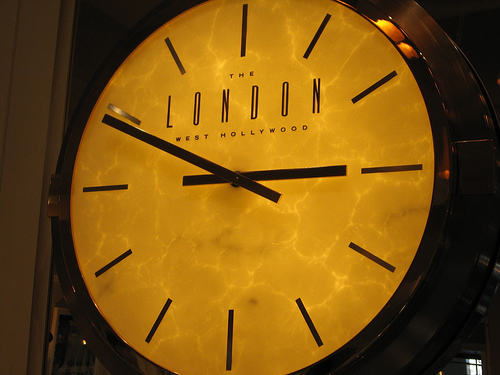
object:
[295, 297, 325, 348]
line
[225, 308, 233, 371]
line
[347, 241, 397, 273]
line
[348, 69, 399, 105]
line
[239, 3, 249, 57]
line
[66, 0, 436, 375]
clock face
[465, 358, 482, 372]
window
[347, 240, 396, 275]
tick mark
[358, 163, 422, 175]
tick mark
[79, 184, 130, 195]
tick mark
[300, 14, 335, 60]
tick mark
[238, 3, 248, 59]
tick mark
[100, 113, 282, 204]
hand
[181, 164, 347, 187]
clock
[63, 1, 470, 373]
metallic clock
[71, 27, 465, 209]
black paint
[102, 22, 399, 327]
face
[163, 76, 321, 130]
lettering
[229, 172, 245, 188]
bolt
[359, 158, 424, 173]
tick mark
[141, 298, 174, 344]
tick mark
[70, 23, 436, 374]
clock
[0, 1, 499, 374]
building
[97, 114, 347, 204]
hand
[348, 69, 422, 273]
numbers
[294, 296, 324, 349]
mark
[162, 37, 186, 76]
mark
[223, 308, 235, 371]
dash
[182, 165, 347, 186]
hand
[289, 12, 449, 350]
reflection